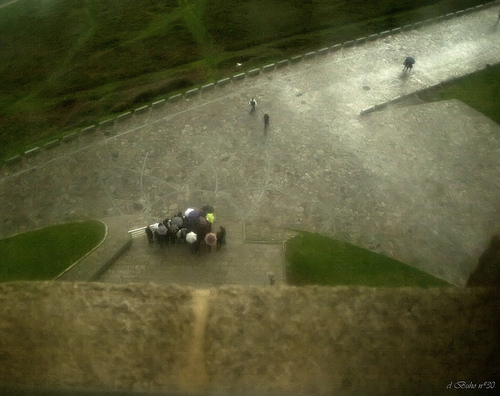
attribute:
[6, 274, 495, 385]
edge — stone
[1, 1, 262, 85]
grass — green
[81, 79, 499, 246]
floor — gray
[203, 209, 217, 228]
umbrella — green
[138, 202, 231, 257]
people — grouped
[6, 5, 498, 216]
road — paved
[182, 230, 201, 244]
umrella — opened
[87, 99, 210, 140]
line — white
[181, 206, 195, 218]
umbrella — white